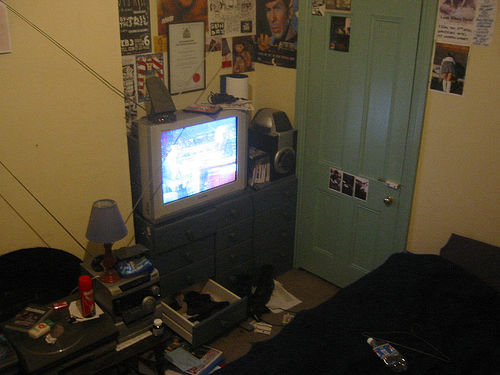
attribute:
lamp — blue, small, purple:
[75, 205, 127, 268]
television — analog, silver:
[134, 112, 260, 208]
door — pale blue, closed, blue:
[295, 5, 415, 280]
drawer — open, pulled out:
[156, 290, 275, 335]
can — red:
[69, 266, 105, 324]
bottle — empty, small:
[357, 332, 411, 368]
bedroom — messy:
[18, 149, 496, 374]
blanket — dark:
[280, 274, 468, 374]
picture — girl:
[434, 44, 473, 95]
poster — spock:
[255, 4, 297, 66]